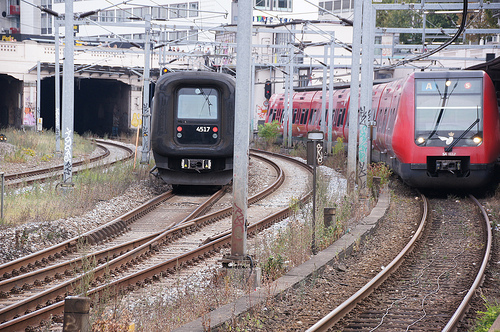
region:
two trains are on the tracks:
[90, 53, 495, 248]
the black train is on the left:
[123, 59, 250, 204]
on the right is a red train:
[363, 43, 495, 218]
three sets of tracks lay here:
[1, 143, 479, 320]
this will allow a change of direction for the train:
[85, 198, 233, 283]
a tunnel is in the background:
[46, 80, 136, 136]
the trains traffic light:
[258, 78, 275, 100]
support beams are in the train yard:
[228, 3, 376, 278]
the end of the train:
[149, 54, 250, 209]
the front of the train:
[381, 56, 495, 203]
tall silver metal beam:
[230, 1, 249, 256]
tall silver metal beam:
[348, 4, 358, 176]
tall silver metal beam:
[363, 1, 375, 171]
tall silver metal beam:
[61, 5, 76, 180]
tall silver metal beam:
[53, 20, 63, 129]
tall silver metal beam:
[139, 26, 150, 154]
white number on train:
[193, 126, 198, 133]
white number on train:
[198, 124, 204, 134]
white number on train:
[201, 125, 208, 133]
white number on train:
[205, 124, 212, 133]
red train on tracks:
[264, 67, 493, 199]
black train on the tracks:
[148, 69, 235, 195]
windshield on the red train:
[416, 89, 479, 143]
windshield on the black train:
[177, 87, 218, 122]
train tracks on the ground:
[300, 193, 495, 330]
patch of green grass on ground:
[475, 304, 492, 326]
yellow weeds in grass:
[192, 272, 274, 321]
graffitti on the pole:
[66, 116, 74, 180]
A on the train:
[422, 76, 438, 91]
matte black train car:
[147, 66, 249, 182]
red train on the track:
[362, 56, 497, 183]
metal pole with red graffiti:
[208, 11, 264, 284]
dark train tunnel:
[26, 73, 152, 148]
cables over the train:
[155, 9, 480, 91]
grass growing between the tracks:
[287, 161, 370, 256]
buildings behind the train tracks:
[56, 0, 374, 60]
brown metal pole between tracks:
[298, 124, 325, 256]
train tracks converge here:
[40, 197, 245, 302]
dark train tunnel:
[0, 60, 37, 137]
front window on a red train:
[414, 79, 481, 147]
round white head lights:
[416, 135, 480, 145]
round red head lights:
[174, 124, 219, 131]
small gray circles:
[176, 131, 220, 141]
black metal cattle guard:
[425, 152, 474, 176]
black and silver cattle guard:
[167, 154, 224, 174]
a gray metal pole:
[232, 2, 252, 262]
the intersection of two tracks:
[113, 209, 216, 268]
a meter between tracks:
[306, 129, 326, 254]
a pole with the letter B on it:
[60, 296, 90, 330]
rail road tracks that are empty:
[2, 136, 135, 186]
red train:
[265, 69, 497, 192]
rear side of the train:
[161, 79, 225, 161]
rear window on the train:
[186, 86, 218, 128]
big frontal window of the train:
[411, 78, 483, 153]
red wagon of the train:
[396, 93, 483, 180]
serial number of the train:
[193, 125, 211, 138]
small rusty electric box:
[307, 133, 329, 164]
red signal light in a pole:
[265, 81, 269, 94]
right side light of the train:
[471, 133, 483, 145]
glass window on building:
[38, 10, 45, 32]